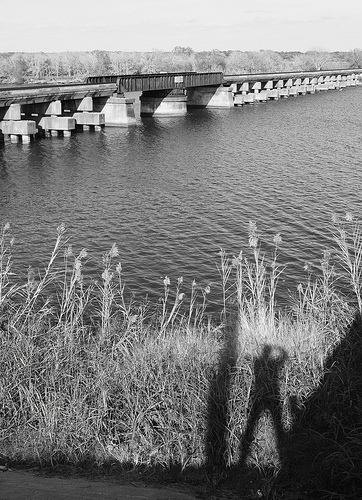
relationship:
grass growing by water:
[0, 215, 350, 474] [1, 95, 361, 314]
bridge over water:
[0, 68, 361, 148] [0, 87, 351, 324]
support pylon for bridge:
[20, 99, 75, 139] [0, 68, 361, 148]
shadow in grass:
[239, 338, 289, 464] [0, 215, 350, 474]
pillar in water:
[138, 90, 191, 120] [0, 87, 351, 324]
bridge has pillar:
[0, 68, 361, 148] [138, 90, 191, 120]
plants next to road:
[4, 209, 350, 484] [1, 459, 350, 497]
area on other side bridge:
[2, 51, 349, 85] [0, 68, 361, 148]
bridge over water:
[0, 61, 346, 149] [0, 78, 349, 343]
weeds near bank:
[18, 250, 301, 367] [1, 305, 338, 405]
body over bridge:
[0, 86, 347, 328] [0, 61, 346, 149]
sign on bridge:
[168, 66, 187, 88] [6, 51, 349, 153]